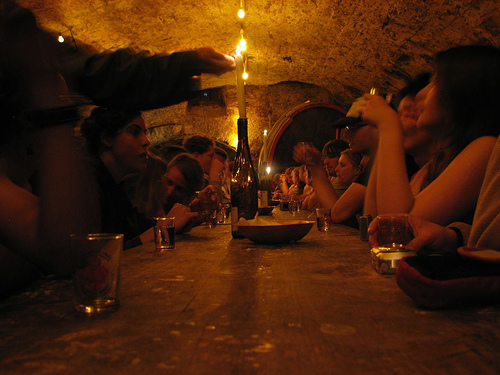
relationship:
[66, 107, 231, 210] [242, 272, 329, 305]
people are around table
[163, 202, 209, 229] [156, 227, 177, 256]
hand holding glass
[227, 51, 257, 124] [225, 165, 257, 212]
candle in bottle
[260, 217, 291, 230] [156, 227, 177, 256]
liquid in glass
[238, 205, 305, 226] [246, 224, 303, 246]
snacks are in bowl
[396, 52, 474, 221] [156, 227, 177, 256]
woman holding glass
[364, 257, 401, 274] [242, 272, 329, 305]
plate on table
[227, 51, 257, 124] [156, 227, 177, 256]
candle in glass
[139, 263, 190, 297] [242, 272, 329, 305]
stains are on table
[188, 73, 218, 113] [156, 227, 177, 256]
alcohol in glass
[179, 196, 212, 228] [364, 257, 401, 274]
food on plate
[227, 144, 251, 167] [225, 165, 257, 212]
wine in bottle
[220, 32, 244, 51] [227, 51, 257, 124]
flame on candle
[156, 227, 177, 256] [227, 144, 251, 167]
glass for wine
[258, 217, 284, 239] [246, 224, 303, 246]
snacks are in bowl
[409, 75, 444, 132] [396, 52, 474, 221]
face of woman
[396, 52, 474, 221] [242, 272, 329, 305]
woman at table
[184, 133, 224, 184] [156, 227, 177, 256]
person holding glass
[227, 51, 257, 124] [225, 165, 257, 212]
candle inside bottle